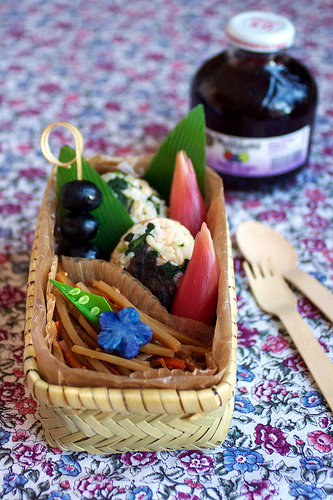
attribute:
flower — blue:
[94, 302, 152, 360]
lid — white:
[225, 10, 295, 53]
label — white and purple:
[196, 119, 320, 187]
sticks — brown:
[57, 320, 97, 355]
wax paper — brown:
[47, 149, 213, 382]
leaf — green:
[173, 105, 207, 149]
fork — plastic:
[239, 259, 332, 405]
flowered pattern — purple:
[13, 19, 157, 115]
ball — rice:
[109, 216, 200, 310]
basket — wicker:
[21, 250, 68, 377]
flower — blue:
[96, 300, 155, 344]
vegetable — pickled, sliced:
[94, 278, 180, 350]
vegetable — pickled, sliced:
[69, 342, 154, 373]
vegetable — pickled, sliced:
[52, 293, 105, 372]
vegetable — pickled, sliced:
[157, 352, 185, 365]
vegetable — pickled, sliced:
[57, 336, 83, 369]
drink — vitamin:
[192, 51, 316, 181]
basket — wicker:
[20, 143, 241, 457]